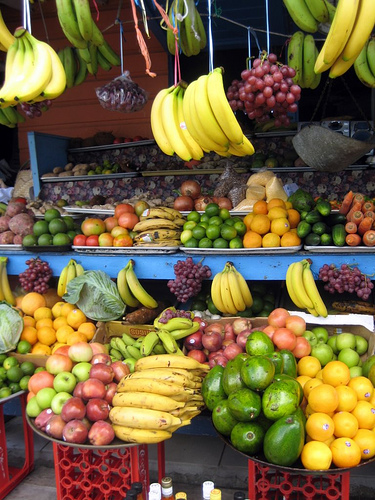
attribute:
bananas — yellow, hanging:
[156, 62, 257, 161]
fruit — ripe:
[1, 197, 370, 475]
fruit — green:
[179, 198, 244, 247]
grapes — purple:
[166, 254, 213, 306]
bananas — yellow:
[208, 259, 255, 315]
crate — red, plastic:
[47, 431, 171, 497]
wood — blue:
[5, 252, 374, 284]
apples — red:
[187, 314, 257, 362]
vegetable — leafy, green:
[66, 270, 130, 326]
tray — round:
[21, 427, 172, 454]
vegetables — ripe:
[3, 189, 372, 249]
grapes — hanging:
[235, 45, 302, 125]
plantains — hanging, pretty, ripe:
[53, 4, 130, 83]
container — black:
[21, 244, 74, 254]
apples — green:
[27, 365, 93, 410]